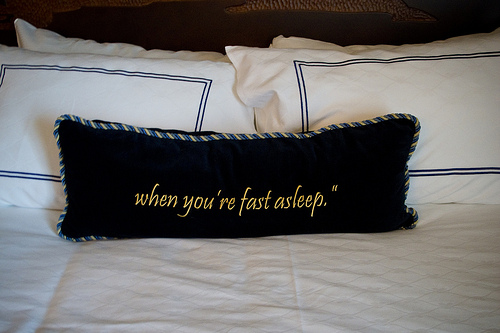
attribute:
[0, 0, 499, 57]
brown headboard — wooden 